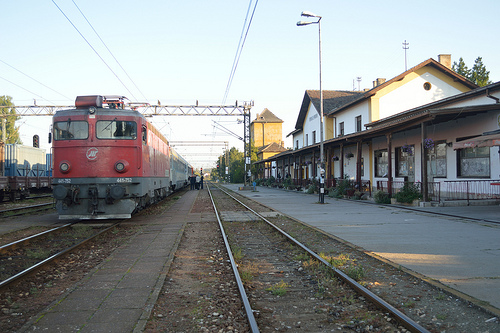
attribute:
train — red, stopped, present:
[51, 96, 197, 223]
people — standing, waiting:
[188, 174, 204, 190]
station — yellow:
[250, 53, 497, 203]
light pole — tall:
[293, 9, 328, 206]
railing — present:
[376, 180, 442, 204]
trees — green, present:
[451, 57, 494, 87]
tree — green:
[1, 91, 26, 144]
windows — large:
[55, 119, 138, 142]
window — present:
[393, 142, 418, 178]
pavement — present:
[227, 179, 500, 313]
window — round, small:
[422, 81, 433, 91]